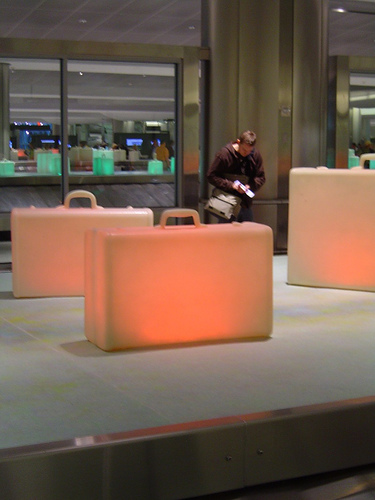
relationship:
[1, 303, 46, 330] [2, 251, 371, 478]
yellow paint on platform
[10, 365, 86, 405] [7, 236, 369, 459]
paint on platform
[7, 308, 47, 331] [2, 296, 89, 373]
yellow paint on platform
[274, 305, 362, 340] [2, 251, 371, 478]
paint on platform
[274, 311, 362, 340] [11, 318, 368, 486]
paint on platform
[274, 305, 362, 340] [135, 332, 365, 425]
paint on platform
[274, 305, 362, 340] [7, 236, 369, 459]
paint on platform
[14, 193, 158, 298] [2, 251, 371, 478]
briefcase on platform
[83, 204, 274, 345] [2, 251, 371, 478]
briefcase on platform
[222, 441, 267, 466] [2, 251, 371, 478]
nails in platform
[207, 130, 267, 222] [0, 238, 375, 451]
person standing on sidewalk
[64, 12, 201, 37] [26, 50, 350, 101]
lighting on ceiling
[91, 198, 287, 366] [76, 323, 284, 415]
briefcase on platform